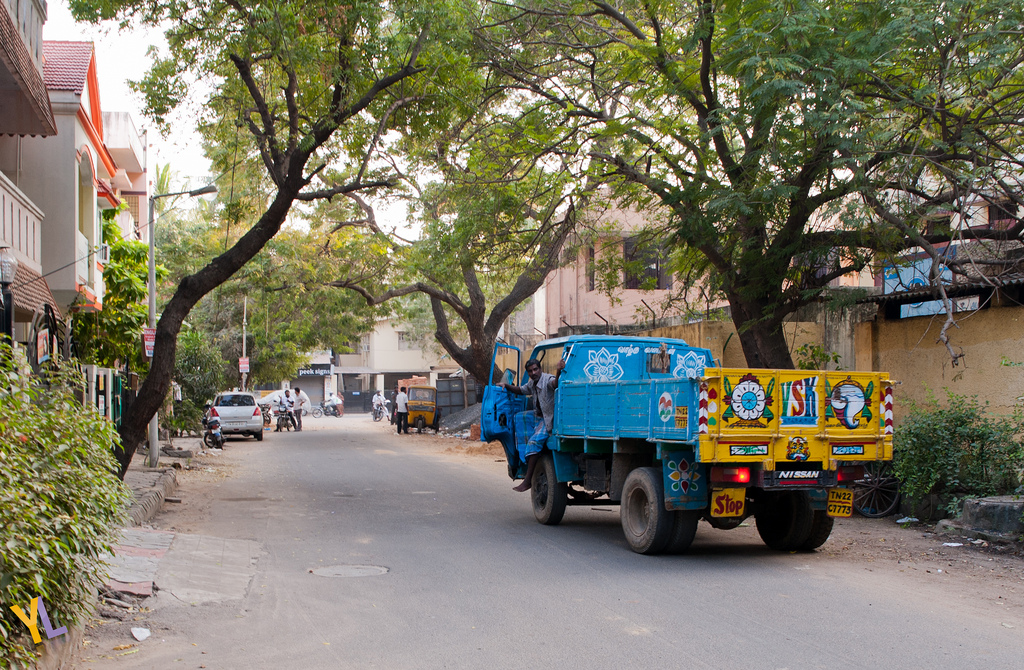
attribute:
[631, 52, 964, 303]
leaves — green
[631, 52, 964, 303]
healthy leaves — green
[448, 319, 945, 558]
blue truck — yellow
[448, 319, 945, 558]
parked truck — blue, yellow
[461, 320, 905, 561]
truck parked — yellow, blue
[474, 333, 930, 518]
truck — blue, yellow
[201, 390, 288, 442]
car — white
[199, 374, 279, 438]
car — white